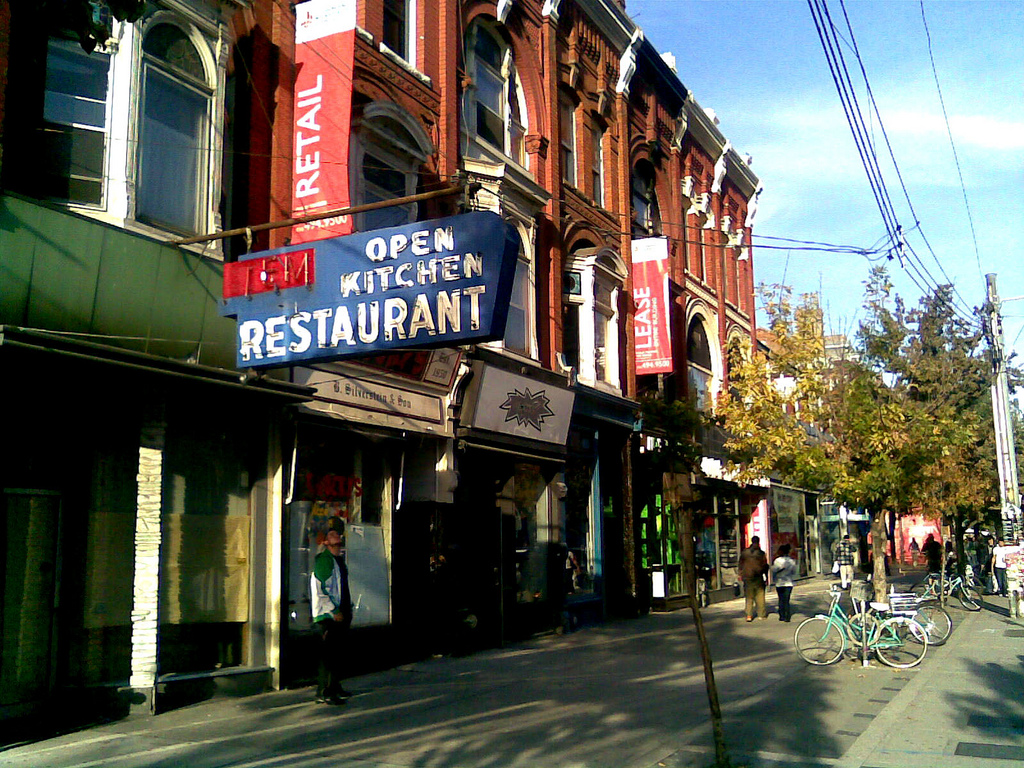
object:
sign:
[217, 210, 523, 368]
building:
[0, 0, 759, 748]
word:
[238, 224, 485, 361]